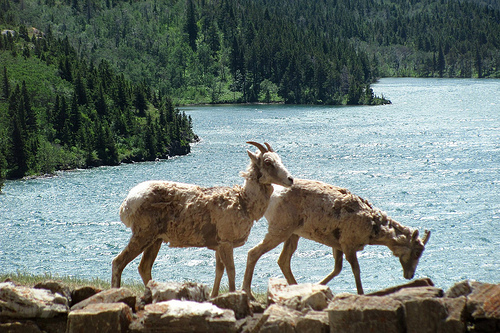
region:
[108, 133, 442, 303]
the goats are dirty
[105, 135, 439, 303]
these are goats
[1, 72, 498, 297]
the water is calm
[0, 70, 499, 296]
the water is reflecting the blue sky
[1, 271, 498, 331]
the rocks are brown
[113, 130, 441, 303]
the goats are on the rocks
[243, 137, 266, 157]
this is a horn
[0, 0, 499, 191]
the trees are lush and green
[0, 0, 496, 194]
the trees are covering the mountains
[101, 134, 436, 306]
the goats are standing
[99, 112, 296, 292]
A goat on a damn wall.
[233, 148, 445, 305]
a goat sniffing rocks.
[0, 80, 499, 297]
a large body of water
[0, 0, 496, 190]
a forest filled with leafy green trees.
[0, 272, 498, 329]
A rock wall damn.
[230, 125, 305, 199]
a long horned goat.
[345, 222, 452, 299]
a goat looking down.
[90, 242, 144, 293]
a back right foot.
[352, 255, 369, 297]
a front left foot.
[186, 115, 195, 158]
a tree near the water.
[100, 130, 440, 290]
two goats next to a river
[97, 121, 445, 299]
two goats color brown and white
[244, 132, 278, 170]
goat has two hornes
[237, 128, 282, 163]
goats are bend backwards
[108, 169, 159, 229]
part of goat is white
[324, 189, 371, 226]
dark brown spots on goat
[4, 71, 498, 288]
water of river is color blue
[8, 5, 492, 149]
green pines on the mountain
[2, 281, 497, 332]
rocks on the shore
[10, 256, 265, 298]
green grass near the rocks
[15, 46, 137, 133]
Trees are green color.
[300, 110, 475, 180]
Water is blue color.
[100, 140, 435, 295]
Two sheep are standing in the rock.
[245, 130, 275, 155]
Two horns are there in sheep.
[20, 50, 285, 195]
Trees are behind the water.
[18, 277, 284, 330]
Rocks are brown color.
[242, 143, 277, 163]
Two pointed ears for sheep.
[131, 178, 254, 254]
Sheep wool is removed.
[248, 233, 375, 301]
Sheep has four legs.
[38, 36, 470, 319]
Day time picture.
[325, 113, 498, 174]
A patch of simmering water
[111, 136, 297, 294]
A very shedding goat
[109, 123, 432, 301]
A pair of goats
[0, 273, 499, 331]
A bunch of rocks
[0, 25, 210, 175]
Green trees on a hill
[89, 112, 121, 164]
A full green tree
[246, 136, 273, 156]
A pair of goat horns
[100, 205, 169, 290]
A goat's pair of hine legs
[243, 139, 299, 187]
A white goats head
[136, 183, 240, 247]
Shedding goat wool